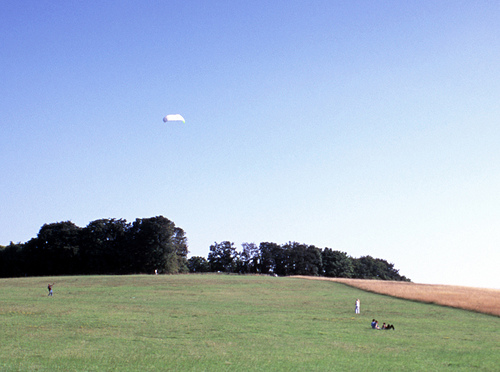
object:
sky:
[0, 0, 499, 290]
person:
[353, 298, 361, 313]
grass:
[290, 275, 499, 318]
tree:
[0, 213, 189, 279]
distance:
[0, 168, 499, 302]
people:
[380, 322, 396, 330]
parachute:
[160, 114, 185, 124]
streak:
[367, 168, 456, 195]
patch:
[283, 273, 500, 316]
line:
[383, 291, 456, 305]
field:
[0, 212, 499, 371]